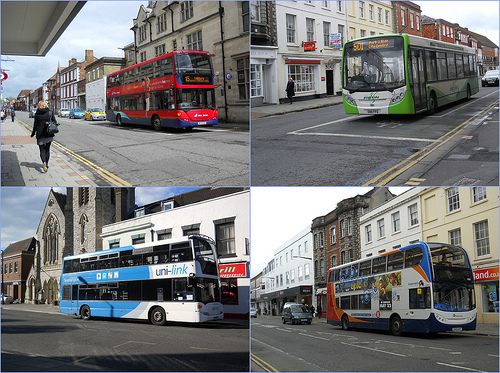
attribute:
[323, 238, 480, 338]
bus — red, white, blue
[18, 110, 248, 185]
road — light gray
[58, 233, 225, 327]
bus — blue, double-decker, red, green, white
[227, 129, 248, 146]
water — blue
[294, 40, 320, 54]
sign — red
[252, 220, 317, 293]
building — white, brick